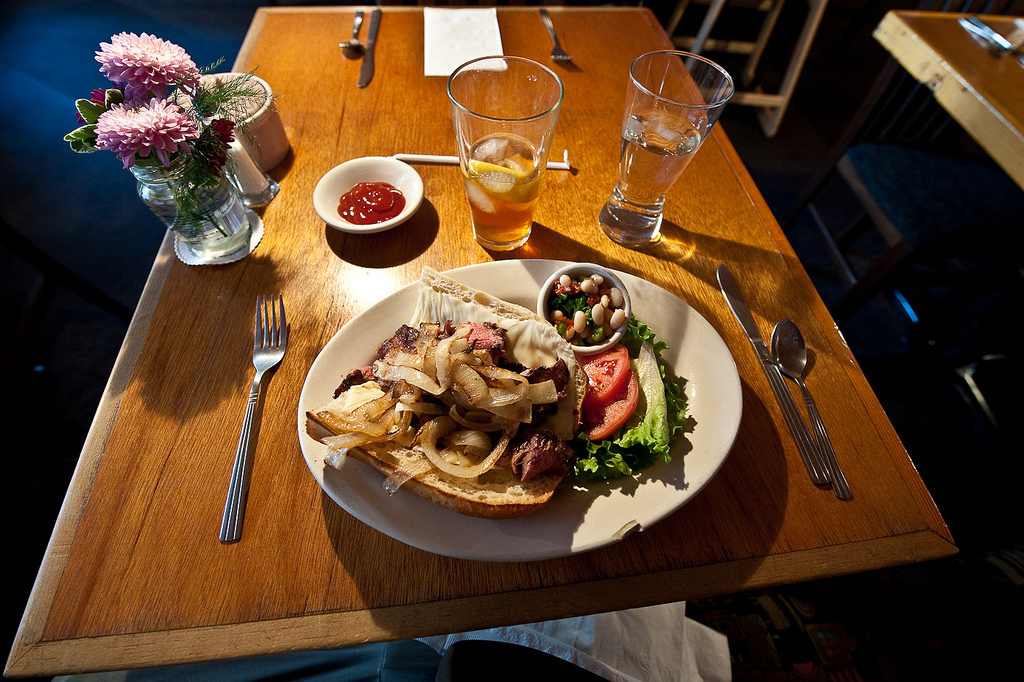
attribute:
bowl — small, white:
[313, 152, 422, 226]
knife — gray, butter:
[350, 4, 388, 90]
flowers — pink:
[69, 22, 250, 260]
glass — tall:
[603, 41, 734, 270]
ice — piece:
[477, 134, 507, 167]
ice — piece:
[518, 151, 525, 190]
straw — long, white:
[392, 139, 569, 174]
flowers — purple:
[79, 23, 254, 249]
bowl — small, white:
[310, 151, 424, 232]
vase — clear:
[44, 22, 273, 261]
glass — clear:
[590, 40, 731, 247]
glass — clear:
[434, 44, 565, 253]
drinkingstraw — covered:
[384, 140, 574, 173]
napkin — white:
[412, 599, 742, 680]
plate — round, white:
[297, 256, 751, 572]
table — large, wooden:
[3, 3, 969, 678]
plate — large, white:
[277, 253, 764, 560]